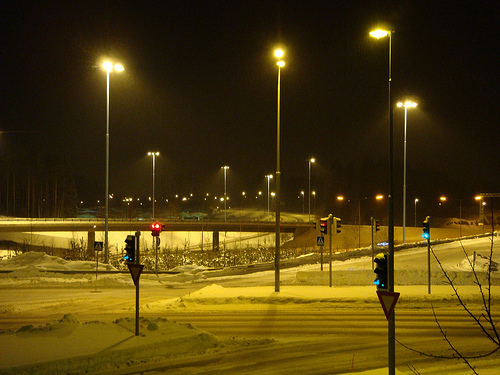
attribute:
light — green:
[371, 276, 385, 286]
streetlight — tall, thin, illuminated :
[262, 38, 294, 293]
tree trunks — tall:
[0, 168, 78, 216]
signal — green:
[413, 361, 450, 373]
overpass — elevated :
[19, 205, 288, 270]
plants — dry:
[115, 238, 272, 265]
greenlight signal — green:
[419, 217, 432, 241]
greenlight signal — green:
[369, 250, 395, 294]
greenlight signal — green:
[121, 231, 139, 266]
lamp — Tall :
[92, 44, 375, 74]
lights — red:
[146, 221, 161, 233]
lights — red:
[149, 216, 166, 235]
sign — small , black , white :
[91, 237, 106, 252]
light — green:
[122, 252, 137, 266]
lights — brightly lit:
[89, 53, 131, 75]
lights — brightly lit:
[266, 43, 288, 69]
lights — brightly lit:
[365, 25, 390, 42]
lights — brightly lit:
[392, 95, 417, 111]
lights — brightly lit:
[142, 148, 164, 158]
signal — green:
[388, 93, 454, 134]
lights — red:
[150, 223, 160, 228]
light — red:
[148, 219, 161, 239]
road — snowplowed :
[136, 272, 438, 354]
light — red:
[149, 221, 155, 231]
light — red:
[153, 219, 162, 231]